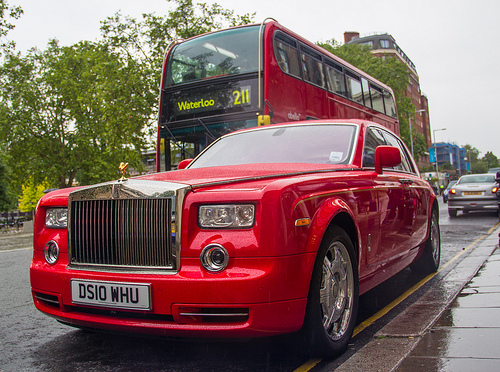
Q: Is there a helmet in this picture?
A: No, there are no helmets.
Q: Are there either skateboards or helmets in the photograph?
A: No, there are no helmets or skateboards.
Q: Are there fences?
A: No, there are no fences.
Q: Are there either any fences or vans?
A: No, there are no fences or vans.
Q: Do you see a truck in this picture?
A: No, there are no trucks.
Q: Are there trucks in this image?
A: No, there are no trucks.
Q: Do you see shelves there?
A: No, there are no shelves.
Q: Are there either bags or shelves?
A: No, there are no shelves or bags.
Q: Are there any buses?
A: Yes, there is a bus.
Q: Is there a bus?
A: Yes, there is a bus.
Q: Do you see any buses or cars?
A: Yes, there is a bus.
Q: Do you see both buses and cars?
A: Yes, there are both a bus and a car.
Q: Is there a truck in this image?
A: No, there are no trucks.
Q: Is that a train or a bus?
A: That is a bus.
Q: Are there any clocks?
A: No, there are no clocks.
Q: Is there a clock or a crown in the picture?
A: No, there are no clocks or crowns.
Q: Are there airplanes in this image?
A: No, there are no airplanes.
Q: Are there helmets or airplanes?
A: No, there are no airplanes or helmets.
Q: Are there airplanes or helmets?
A: No, there are no airplanes or helmets.